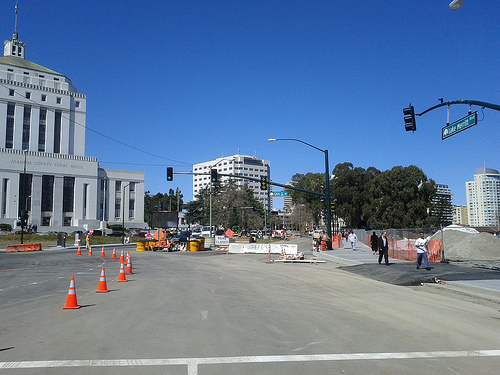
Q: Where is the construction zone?
A: Behind the barriers.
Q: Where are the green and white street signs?
A: Hanging from the traffic light poles.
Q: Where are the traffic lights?
A: Above the street.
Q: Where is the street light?
A: High over the street.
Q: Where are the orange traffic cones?
A: On the street.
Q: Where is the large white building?
A: On the right.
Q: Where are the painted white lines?
A: On the street.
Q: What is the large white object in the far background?
A: Tall building.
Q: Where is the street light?
A: Near traffic signal.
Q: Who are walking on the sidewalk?
A: 2 men.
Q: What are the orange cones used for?
A: Signaling traffic.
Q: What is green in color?
A: Traffic signals.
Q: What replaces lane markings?
A: Orange cones.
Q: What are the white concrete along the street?
A: Buildings.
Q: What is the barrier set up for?
A: Keeping traffic out.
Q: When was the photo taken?
A: Daytime.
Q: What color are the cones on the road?
A: Orange and white.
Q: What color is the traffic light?
A: Green.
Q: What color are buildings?
A: Gray.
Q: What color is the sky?
A: Blue.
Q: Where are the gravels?
A: Right side of the image.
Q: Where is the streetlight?
A: Over the traffic light.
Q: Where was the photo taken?
A: On the street.